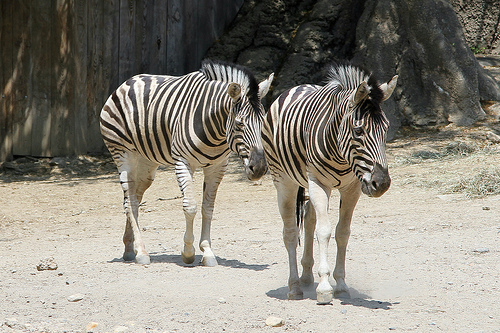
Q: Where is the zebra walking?
A: In the dirt.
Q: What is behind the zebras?
A: A brown tree trunk.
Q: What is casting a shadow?
A: A tree.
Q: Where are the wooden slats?
A: On the fence.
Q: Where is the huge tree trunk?
A: Behind the zebras.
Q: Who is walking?
A: A black and white zebra.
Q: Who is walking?
A: The zebra on the right.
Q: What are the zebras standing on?
A: Dirt ground.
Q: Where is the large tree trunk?
A: Behind the zebras.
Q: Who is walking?
A: Two zebras.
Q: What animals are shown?
A: Zebras.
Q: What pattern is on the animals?
A: Stripes.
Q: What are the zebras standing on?
A: Dirt.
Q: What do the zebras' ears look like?
A: Standing up.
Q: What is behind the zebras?
A: A wall.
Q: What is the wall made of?
A: Wood.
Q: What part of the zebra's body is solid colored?
A: Feet and legs.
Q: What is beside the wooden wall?
A: A large tree trunk.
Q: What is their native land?
A: Africa.